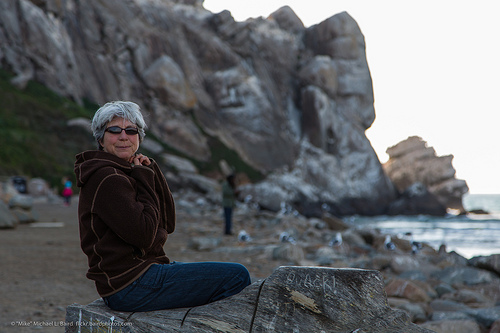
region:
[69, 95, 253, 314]
woman sitting on a rock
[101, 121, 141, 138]
black pair of sunglasses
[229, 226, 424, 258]
five seagulls on the rocks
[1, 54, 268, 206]
a slope covered in vegetation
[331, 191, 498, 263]
a body of water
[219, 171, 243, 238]
a person standing on the beach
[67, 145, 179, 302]
brown hoodie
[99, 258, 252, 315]
blue pair of jeans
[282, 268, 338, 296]
the word "QUACK" carved into the rock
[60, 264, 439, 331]
a large rock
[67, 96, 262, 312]
woman wearing a brown jacket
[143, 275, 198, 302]
blue jeans the woman has on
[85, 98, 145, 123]
gray hair of the lady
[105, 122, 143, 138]
black sunglasses on the woman's face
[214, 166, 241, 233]
person in green jacket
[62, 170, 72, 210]
blue and pink in the background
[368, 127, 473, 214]
big rock formations out in the water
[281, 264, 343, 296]
saying on the rock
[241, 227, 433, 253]
birds on the rocks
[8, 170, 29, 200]
blurry person standing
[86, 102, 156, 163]
A woman in glasses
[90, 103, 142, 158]
A woman in sun glasses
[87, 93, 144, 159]
A woman in dark shades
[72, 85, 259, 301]
A woman sitting down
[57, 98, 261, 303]
A woman sitting outside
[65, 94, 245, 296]
A woman sitting down on a tree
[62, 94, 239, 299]
A woman in a hoodie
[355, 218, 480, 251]
the ocean water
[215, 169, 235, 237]
a person in a green coat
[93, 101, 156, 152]
A woman with peppered hair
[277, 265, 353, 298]
Quack is written on rock.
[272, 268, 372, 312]
Rock is engraved with Quack.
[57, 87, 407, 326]
Woman is sitting on rock.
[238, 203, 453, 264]
Ducks stand in the distance.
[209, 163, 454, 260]
A man is feeding ducks.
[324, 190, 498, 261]
Ducks around a shoreline.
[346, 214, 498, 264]
Water is calm.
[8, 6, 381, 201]
Large rock formations overlook shore.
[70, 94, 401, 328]
Elderly woman rests on rock.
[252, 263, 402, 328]
Rock has been vandalized.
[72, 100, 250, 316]
Happy woman sitting on a large rock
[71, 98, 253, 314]
Older woman wearing a brown sweatshirt and blue jeans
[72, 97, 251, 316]
Older woman with short grey hair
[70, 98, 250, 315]
Sitting woman with gray hair and dark sunglasses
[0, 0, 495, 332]
Rocky scenery next to a lake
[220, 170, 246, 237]
Dark person on a rocky shore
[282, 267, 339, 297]
Letters carved in stone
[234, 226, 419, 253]
Seagulls on a rocky shore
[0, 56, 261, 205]
Grass area in a rocky landscape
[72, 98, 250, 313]
Happy woman with her arms folded upwards